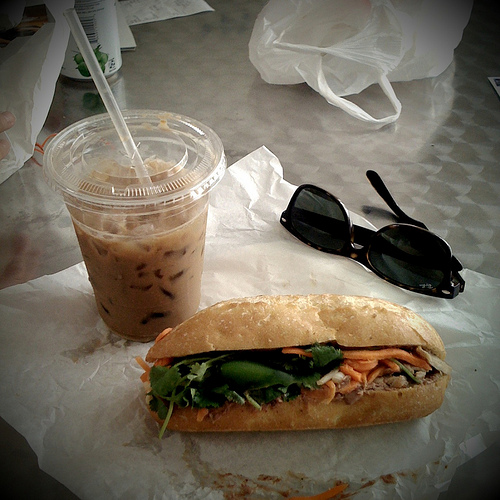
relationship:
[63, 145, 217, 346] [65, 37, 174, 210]
coffee with straw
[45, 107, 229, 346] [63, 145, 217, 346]
cup of coffee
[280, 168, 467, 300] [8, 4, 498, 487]
sunglasses on table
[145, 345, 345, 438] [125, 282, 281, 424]
lettuce on end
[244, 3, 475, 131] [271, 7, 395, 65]
bag with handle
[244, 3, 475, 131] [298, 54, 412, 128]
bag with handle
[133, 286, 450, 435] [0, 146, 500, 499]
bun on paper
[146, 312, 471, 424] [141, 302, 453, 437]
carrots on sandwich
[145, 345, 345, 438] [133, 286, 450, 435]
lettuce on bun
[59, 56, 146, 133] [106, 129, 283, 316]
straw in cup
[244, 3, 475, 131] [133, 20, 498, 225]
bag on table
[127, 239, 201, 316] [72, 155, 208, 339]
ice in coffee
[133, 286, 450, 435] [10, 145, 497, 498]
bun on wrapper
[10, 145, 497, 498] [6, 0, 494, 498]
wrapper on counter top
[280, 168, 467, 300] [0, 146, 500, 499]
sunglasses on paper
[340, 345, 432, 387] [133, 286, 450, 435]
shredded cheese on bun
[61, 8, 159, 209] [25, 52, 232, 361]
straw in cup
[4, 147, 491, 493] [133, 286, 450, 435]
paper under bun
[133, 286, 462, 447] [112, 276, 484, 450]
bun used for sandwich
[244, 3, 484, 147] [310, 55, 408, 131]
bag has handle